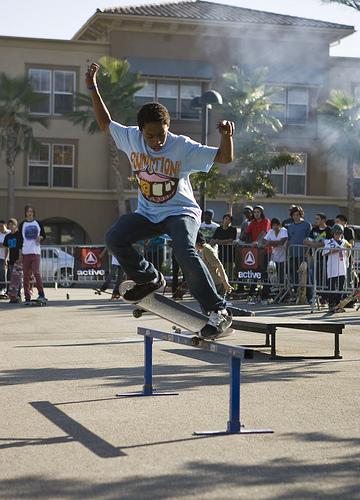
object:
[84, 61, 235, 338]
boy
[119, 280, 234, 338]
skateboard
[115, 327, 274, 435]
ramp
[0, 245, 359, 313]
fence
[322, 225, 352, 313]
boy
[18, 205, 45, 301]
man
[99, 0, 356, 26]
roof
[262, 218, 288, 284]
person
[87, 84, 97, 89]
wristband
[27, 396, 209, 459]
shadow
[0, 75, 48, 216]
tree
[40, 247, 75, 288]
car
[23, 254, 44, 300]
pants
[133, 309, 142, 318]
wheel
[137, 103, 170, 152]
head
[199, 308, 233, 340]
shoe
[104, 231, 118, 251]
knee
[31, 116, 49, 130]
leaves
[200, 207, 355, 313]
crowd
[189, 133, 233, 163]
left arm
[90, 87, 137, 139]
right arm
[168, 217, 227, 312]
left leg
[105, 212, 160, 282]
right leg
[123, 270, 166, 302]
shoe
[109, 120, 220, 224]
shirt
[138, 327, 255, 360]
rail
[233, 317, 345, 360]
table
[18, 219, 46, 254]
shirt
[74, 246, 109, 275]
advertisement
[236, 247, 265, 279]
sign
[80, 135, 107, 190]
wall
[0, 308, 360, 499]
court